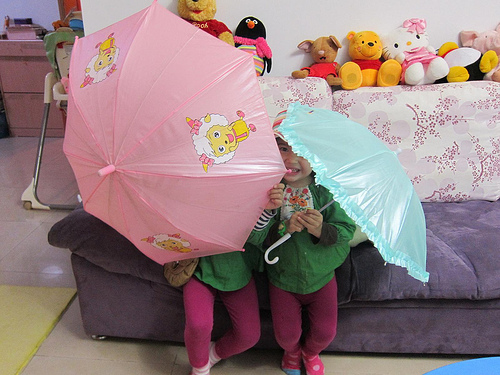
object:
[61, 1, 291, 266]
umbrella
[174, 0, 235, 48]
animal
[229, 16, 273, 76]
animal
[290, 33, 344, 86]
animal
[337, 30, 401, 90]
animal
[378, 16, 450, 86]
animal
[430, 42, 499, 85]
animal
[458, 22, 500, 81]
animal_corner